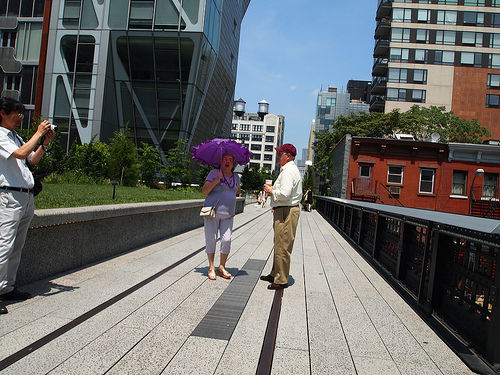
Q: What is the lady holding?
A: An umbrella.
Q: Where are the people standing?
A: On a bridge.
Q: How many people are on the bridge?
A: 3.